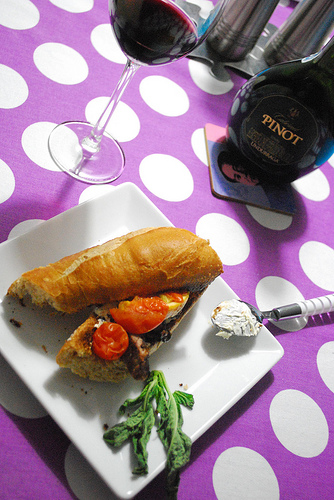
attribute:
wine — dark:
[108, 0, 198, 67]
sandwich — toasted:
[8, 222, 224, 384]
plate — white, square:
[1, 181, 285, 500]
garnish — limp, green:
[104, 367, 195, 476]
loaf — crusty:
[8, 225, 223, 312]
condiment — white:
[212, 298, 261, 342]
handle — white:
[298, 287, 333, 317]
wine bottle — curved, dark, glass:
[226, 30, 333, 180]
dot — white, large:
[137, 151, 193, 206]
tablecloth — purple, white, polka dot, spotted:
[0, 0, 333, 499]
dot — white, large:
[193, 210, 250, 267]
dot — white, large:
[31, 40, 91, 86]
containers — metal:
[207, 0, 332, 62]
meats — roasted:
[96, 304, 173, 378]